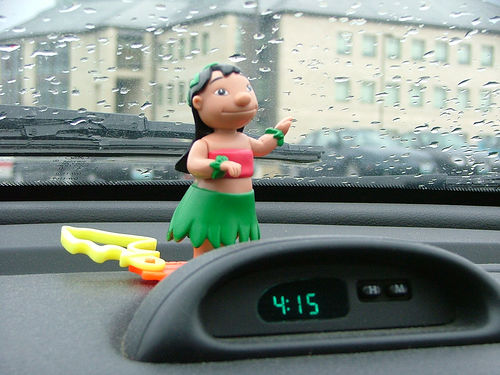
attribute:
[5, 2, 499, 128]
building — large